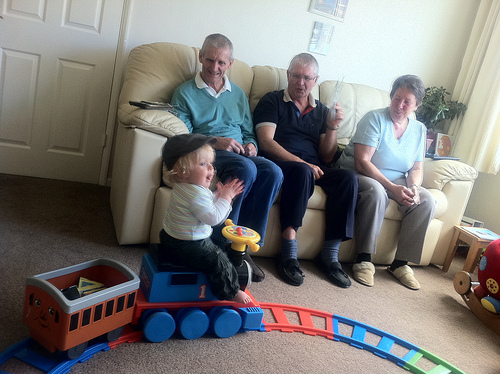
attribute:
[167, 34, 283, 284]
man — sitting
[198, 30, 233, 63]
hair — gray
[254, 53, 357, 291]
man — sitting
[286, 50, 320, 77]
hair — gray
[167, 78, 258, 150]
sweater — blue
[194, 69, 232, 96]
shirt — white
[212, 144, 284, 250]
jeans — blue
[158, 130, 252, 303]
child — baby, light skinned, little, barefoot, clapping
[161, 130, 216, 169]
hat — dark, black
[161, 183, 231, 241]
shirt — white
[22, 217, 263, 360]
train — blue, yellow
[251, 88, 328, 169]
shirt — black, navy blue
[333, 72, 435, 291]
woman — sitting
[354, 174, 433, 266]
pants — khaki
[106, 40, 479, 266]
couch — light beige, beige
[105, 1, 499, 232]
wall — white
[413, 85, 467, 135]
plant — green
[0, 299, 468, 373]
tracks — red blue, green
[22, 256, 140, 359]
train car — orange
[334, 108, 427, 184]
shirt — light blue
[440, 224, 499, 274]
table — very short, wooden, small